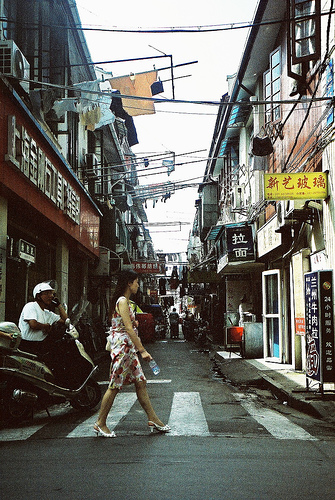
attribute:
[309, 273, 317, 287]
character — whte, foreign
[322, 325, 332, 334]
foreing character — white, foreign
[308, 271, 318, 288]
sign — foreign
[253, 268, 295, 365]
door — glass, open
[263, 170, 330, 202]
sign — Yellow 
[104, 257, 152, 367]
woman — black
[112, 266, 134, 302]
hair — long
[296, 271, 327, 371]
sign — blue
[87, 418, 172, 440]
dress shoes — White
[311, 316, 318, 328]
character — white 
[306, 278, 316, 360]
foreign character — white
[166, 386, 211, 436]
line — white, painted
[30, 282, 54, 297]
helmet — white